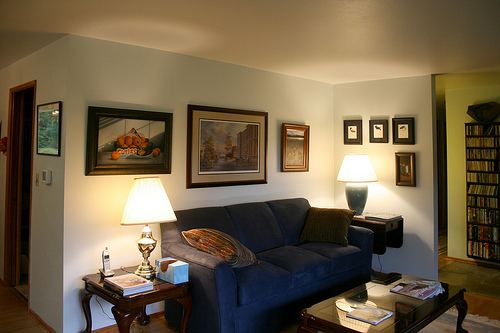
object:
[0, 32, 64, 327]
hallway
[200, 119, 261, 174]
paintings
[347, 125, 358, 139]
pictures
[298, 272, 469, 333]
coffe table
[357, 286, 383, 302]
glass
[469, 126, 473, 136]
books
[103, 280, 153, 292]
book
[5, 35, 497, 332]
living room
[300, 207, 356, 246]
pillow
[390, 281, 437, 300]
magazines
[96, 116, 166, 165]
painting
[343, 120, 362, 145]
cards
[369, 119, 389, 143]
cards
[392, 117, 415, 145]
cards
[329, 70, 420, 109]
wall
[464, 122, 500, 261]
bookshelf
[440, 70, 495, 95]
wall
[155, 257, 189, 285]
box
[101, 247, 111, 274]
phone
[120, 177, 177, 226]
lampshade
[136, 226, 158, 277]
base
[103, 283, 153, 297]
book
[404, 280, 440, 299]
newspaper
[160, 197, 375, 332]
couch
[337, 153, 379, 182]
lampshade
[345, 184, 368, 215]
base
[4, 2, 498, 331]
room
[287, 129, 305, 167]
pictures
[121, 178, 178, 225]
lamp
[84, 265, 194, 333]
table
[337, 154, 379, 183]
lamp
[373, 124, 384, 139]
pictures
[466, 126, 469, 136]
book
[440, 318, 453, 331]
rug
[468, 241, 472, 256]
books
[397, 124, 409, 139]
pictures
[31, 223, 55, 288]
wall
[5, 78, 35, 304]
door way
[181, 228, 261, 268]
pillow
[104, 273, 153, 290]
book